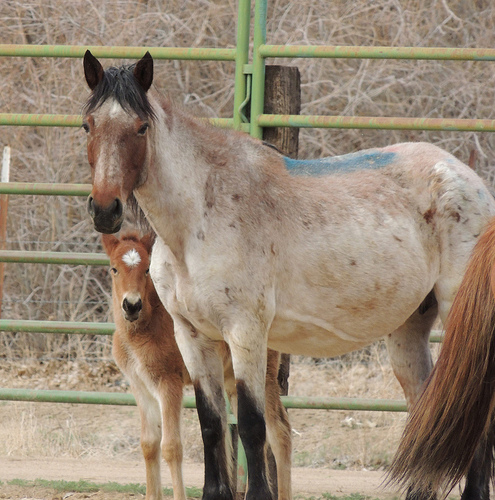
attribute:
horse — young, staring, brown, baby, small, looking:
[95, 219, 314, 499]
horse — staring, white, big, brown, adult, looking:
[68, 40, 494, 500]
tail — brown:
[386, 207, 492, 498]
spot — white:
[115, 246, 148, 270]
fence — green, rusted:
[2, 15, 488, 423]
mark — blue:
[271, 141, 407, 184]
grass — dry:
[2, 5, 493, 383]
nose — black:
[119, 295, 148, 318]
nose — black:
[83, 197, 128, 229]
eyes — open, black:
[107, 260, 154, 277]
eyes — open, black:
[77, 113, 152, 139]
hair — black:
[80, 62, 151, 126]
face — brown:
[104, 243, 158, 327]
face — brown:
[76, 85, 160, 243]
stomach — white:
[258, 281, 449, 356]